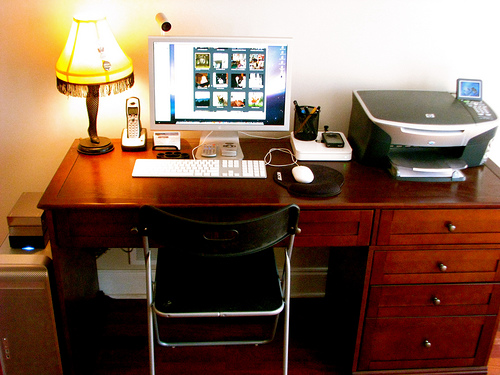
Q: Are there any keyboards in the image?
A: Yes, there is a keyboard.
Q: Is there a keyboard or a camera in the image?
A: Yes, there is a keyboard.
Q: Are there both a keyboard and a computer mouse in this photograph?
A: Yes, there are both a keyboard and a computer mouse.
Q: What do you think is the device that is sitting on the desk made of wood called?
A: The device is a keyboard.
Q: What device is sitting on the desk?
A: The device is a keyboard.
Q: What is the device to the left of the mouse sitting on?
A: The keyboard is sitting on the desk.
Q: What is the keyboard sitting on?
A: The keyboard is sitting on the desk.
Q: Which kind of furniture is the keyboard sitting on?
A: The keyboard is sitting on the desk.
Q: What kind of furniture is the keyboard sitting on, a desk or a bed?
A: The keyboard is sitting on a desk.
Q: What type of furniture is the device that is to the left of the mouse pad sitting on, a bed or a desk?
A: The keyboard is sitting on a desk.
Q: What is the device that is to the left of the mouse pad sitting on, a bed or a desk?
A: The keyboard is sitting on a desk.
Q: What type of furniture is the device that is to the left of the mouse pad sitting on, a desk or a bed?
A: The keyboard is sitting on a desk.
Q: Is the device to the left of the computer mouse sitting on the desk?
A: Yes, the keyboard is sitting on the desk.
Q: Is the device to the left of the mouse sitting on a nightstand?
A: No, the keyboard is sitting on the desk.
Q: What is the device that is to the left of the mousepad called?
A: The device is a keyboard.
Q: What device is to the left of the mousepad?
A: The device is a keyboard.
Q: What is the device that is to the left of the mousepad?
A: The device is a keyboard.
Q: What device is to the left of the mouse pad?
A: The device is a keyboard.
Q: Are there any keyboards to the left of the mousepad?
A: Yes, there is a keyboard to the left of the mousepad.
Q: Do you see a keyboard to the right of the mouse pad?
A: No, the keyboard is to the left of the mouse pad.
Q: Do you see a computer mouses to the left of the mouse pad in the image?
A: No, there is a keyboard to the left of the mouse pad.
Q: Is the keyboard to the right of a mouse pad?
A: No, the keyboard is to the left of a mouse pad.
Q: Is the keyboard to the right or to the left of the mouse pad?
A: The keyboard is to the left of the mouse pad.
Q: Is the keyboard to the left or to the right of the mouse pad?
A: The keyboard is to the left of the mouse pad.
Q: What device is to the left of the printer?
A: The device is a keyboard.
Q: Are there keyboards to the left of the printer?
A: Yes, there is a keyboard to the left of the printer.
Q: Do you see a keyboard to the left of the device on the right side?
A: Yes, there is a keyboard to the left of the printer.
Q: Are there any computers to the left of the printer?
A: No, there is a keyboard to the left of the printer.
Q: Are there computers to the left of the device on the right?
A: No, there is a keyboard to the left of the printer.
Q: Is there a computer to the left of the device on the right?
A: No, there is a keyboard to the left of the printer.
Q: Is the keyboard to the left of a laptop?
A: No, the keyboard is to the left of the printer.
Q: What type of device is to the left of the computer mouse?
A: The device is a keyboard.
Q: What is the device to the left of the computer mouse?
A: The device is a keyboard.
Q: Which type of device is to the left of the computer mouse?
A: The device is a keyboard.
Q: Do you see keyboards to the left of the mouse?
A: Yes, there is a keyboard to the left of the mouse.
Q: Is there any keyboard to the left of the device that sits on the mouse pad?
A: Yes, there is a keyboard to the left of the mouse.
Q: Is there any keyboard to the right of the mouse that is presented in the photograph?
A: No, the keyboard is to the left of the mouse.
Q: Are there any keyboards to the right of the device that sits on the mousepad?
A: No, the keyboard is to the left of the mouse.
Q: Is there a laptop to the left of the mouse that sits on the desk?
A: No, there is a keyboard to the left of the mouse.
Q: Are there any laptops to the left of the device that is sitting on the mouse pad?
A: No, there is a keyboard to the left of the mouse.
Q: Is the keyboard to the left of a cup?
A: No, the keyboard is to the left of the mouse.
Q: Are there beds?
A: No, there are no beds.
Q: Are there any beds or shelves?
A: No, there are no beds or shelves.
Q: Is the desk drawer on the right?
A: Yes, the drawer is on the right of the image.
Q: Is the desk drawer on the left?
A: No, the drawer is on the right of the image.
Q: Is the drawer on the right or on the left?
A: The drawer is on the right of the image.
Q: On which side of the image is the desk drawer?
A: The drawer is on the right of the image.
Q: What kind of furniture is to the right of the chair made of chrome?
A: The piece of furniture is a drawer.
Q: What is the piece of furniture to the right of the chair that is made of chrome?
A: The piece of furniture is a drawer.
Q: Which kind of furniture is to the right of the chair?
A: The piece of furniture is a drawer.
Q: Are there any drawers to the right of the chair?
A: Yes, there is a drawer to the right of the chair.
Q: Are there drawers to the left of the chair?
A: No, the drawer is to the right of the chair.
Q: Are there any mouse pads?
A: Yes, there is a mouse pad.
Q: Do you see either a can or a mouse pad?
A: Yes, there is a mouse pad.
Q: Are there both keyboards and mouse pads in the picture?
A: Yes, there are both a mouse pad and a keyboard.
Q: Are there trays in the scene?
A: No, there are no trays.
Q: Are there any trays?
A: No, there are no trays.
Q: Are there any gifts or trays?
A: No, there are no trays or gifts.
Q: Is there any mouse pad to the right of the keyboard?
A: Yes, there is a mouse pad to the right of the keyboard.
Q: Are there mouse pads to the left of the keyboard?
A: No, the mouse pad is to the right of the keyboard.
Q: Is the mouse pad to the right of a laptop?
A: No, the mouse pad is to the right of the keyboard.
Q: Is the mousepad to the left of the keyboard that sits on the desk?
A: No, the mousepad is to the right of the keyboard.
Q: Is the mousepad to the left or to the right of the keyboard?
A: The mousepad is to the right of the keyboard.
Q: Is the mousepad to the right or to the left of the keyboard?
A: The mousepad is to the right of the keyboard.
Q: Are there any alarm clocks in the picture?
A: No, there are no alarm clocks.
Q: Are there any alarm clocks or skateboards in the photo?
A: No, there are no alarm clocks or skateboards.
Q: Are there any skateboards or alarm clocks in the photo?
A: No, there are no alarm clocks or skateboards.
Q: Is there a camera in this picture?
A: Yes, there is a camera.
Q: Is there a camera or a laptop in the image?
A: Yes, there is a camera.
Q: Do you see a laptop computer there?
A: No, there are no laptops.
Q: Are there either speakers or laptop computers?
A: No, there are no laptop computers or speakers.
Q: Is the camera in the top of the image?
A: Yes, the camera is in the top of the image.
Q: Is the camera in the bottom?
A: No, the camera is in the top of the image.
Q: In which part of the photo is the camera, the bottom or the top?
A: The camera is in the top of the image.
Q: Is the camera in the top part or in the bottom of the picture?
A: The camera is in the top of the image.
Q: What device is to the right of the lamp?
A: The device is a camera.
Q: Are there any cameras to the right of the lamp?
A: Yes, there is a camera to the right of the lamp.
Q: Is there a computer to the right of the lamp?
A: No, there is a camera to the right of the lamp.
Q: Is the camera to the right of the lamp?
A: Yes, the camera is to the right of the lamp.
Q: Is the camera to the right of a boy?
A: No, the camera is to the right of the lamp.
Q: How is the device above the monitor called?
A: The device is a camera.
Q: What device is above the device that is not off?
A: The device is a camera.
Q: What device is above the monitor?
A: The device is a camera.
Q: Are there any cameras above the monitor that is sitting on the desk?
A: Yes, there is a camera above the monitor.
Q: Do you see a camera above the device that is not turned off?
A: Yes, there is a camera above the monitor.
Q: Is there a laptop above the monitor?
A: No, there is a camera above the monitor.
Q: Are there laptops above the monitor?
A: No, there is a camera above the monitor.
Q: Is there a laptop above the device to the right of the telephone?
A: No, there is a camera above the monitor.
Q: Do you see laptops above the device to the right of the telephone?
A: No, there is a camera above the monitor.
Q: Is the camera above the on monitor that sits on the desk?
A: Yes, the camera is above the monitor.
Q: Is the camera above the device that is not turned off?
A: Yes, the camera is above the monitor.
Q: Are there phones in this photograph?
A: Yes, there is a phone.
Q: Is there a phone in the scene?
A: Yes, there is a phone.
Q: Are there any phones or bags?
A: Yes, there is a phone.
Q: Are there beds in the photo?
A: No, there are no beds.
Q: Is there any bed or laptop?
A: No, there are no beds or laptops.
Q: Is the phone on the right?
A: No, the phone is on the left of the image.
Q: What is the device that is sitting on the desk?
A: The device is a phone.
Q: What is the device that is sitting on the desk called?
A: The device is a phone.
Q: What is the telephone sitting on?
A: The telephone is sitting on the desk.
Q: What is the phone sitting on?
A: The telephone is sitting on the desk.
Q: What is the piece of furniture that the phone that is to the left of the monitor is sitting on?
A: The piece of furniture is a desk.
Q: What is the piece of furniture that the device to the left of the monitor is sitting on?
A: The piece of furniture is a desk.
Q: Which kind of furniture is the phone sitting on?
A: The telephone is sitting on the desk.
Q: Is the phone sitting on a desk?
A: Yes, the phone is sitting on a desk.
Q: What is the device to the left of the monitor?
A: The device is a phone.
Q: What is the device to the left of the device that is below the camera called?
A: The device is a phone.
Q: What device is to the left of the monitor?
A: The device is a phone.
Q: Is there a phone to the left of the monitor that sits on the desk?
A: Yes, there is a phone to the left of the monitor.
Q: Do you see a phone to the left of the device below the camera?
A: Yes, there is a phone to the left of the monitor.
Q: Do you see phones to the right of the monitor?
A: No, the phone is to the left of the monitor.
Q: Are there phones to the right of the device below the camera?
A: No, the phone is to the left of the monitor.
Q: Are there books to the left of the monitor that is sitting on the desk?
A: No, there is a phone to the left of the monitor.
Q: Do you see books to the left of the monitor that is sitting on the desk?
A: No, there is a phone to the left of the monitor.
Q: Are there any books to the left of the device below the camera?
A: No, there is a phone to the left of the monitor.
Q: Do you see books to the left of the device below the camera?
A: No, there is a phone to the left of the monitor.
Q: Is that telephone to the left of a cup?
A: No, the telephone is to the left of a monitor.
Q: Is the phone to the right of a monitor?
A: No, the phone is to the left of a monitor.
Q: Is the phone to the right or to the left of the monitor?
A: The phone is to the left of the monitor.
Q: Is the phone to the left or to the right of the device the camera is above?
A: The phone is to the left of the monitor.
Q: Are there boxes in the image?
A: No, there are no boxes.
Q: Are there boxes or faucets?
A: No, there are no boxes or faucets.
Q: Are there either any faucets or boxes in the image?
A: No, there are no boxes or faucets.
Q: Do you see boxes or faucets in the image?
A: No, there are no boxes or faucets.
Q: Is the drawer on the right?
A: Yes, the drawer is on the right of the image.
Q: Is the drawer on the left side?
A: No, the drawer is on the right of the image.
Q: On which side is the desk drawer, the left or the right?
A: The drawer is on the right of the image.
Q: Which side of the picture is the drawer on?
A: The drawer is on the right of the image.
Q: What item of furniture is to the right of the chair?
A: The piece of furniture is a drawer.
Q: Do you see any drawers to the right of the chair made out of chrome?
A: Yes, there is a drawer to the right of the chair.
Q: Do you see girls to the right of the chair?
A: No, there is a drawer to the right of the chair.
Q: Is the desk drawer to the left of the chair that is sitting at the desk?
A: No, the drawer is to the right of the chair.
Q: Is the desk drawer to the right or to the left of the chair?
A: The drawer is to the right of the chair.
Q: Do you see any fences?
A: No, there are no fences.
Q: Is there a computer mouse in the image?
A: Yes, there is a computer mouse.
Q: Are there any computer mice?
A: Yes, there is a computer mouse.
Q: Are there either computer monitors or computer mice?
A: Yes, there is a computer mouse.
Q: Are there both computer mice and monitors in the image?
A: Yes, there are both a computer mouse and a monitor.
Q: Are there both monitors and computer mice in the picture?
A: Yes, there are both a computer mouse and a monitor.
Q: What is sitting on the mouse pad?
A: The mouse is sitting on the mouse pad.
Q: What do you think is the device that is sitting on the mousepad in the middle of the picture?
A: The device is a computer mouse.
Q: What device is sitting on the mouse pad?
A: The device is a computer mouse.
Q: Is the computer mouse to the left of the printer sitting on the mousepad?
A: Yes, the mouse is sitting on the mousepad.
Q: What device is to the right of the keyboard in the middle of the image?
A: The device is a computer mouse.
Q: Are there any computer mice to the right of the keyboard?
A: Yes, there is a computer mouse to the right of the keyboard.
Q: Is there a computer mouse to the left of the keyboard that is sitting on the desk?
A: No, the computer mouse is to the right of the keyboard.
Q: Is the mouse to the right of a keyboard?
A: Yes, the mouse is to the right of a keyboard.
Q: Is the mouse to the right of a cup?
A: No, the mouse is to the right of a keyboard.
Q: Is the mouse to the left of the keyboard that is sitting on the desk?
A: No, the mouse is to the right of the keyboard.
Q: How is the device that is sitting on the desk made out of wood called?
A: The device is a computer mouse.